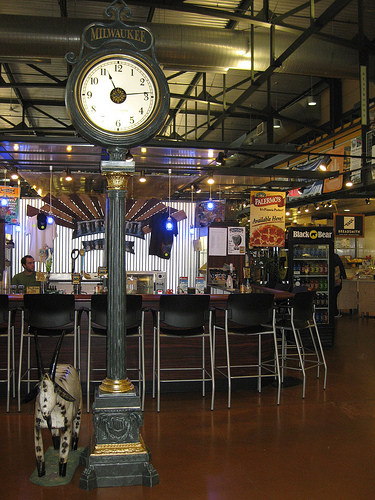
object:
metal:
[99, 377, 134, 393]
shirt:
[12, 271, 41, 293]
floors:
[0, 318, 375, 497]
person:
[334, 252, 347, 318]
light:
[207, 202, 215, 211]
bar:
[0, 140, 335, 394]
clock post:
[64, 0, 169, 489]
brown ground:
[144, 395, 371, 497]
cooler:
[286, 225, 334, 351]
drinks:
[293, 248, 327, 323]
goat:
[20, 330, 83, 477]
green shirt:
[12, 271, 41, 294]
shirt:
[26, 215, 58, 263]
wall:
[11, 195, 198, 290]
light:
[166, 221, 173, 230]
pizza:
[250, 224, 285, 246]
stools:
[150, 292, 281, 414]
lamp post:
[98, 171, 134, 393]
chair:
[149, 294, 217, 413]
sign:
[250, 191, 286, 248]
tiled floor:
[217, 424, 281, 470]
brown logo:
[27, 192, 187, 240]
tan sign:
[27, 191, 187, 240]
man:
[12, 255, 41, 294]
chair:
[275, 291, 327, 400]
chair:
[213, 293, 282, 411]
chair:
[83, 294, 150, 414]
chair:
[18, 292, 83, 412]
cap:
[37, 213, 47, 230]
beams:
[0, 1, 373, 189]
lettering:
[91, 26, 147, 44]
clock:
[64, 17, 170, 149]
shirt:
[149, 212, 179, 260]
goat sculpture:
[20, 330, 83, 477]